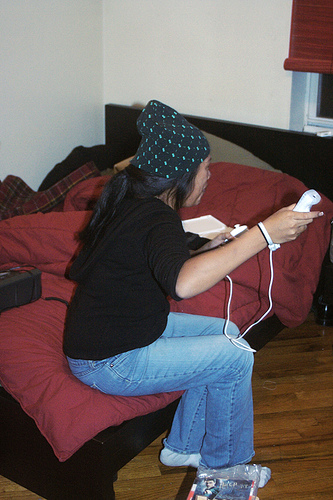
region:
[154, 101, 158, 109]
blue dot on hat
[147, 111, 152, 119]
blue dot on hat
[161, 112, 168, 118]
blue dot on hat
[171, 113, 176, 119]
blue dot on hat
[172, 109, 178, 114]
blue dot on hat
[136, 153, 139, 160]
blue dot on hat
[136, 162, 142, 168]
blue dot on hat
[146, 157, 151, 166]
blue dot on hat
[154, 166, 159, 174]
blue dot on hat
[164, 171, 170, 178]
blue dot on hat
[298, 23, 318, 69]
BLINDS AT THE WINDOW OPEN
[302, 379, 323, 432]
FLOORS ARE MADE OF HARDWOOD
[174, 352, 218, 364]
WOMAN WEARING BLUE JEANS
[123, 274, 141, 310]
LADY HAS ON A BLACK SHIRT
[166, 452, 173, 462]
LADY WEARING SOCKS ON FEET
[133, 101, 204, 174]
SCARF ON THE HEAD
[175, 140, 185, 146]
GREEN SPOTS ON THE SCARF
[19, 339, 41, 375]
BURGANDY BLANKET ON THE BED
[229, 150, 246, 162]
PILLOW UNDER THE COVER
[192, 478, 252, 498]
BOOK ON THE FLOOR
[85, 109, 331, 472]
this is a woman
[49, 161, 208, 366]
woman is wearing a black shirt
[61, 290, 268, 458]
woman wearing blue jeans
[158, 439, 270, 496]
a woman wearing socks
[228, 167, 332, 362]
woman holding a remote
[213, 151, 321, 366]
the remote is white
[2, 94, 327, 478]
woman sitting on a bed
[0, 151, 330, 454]
bed comforter is red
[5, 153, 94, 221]
plaid cover on bed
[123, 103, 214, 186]
woman wearing a hat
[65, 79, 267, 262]
woman wearing a beanie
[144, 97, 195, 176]
green polka dots on benie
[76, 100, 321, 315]
woman holding a wii controller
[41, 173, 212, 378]
woman wearing a black shirt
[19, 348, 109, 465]
red cover on bed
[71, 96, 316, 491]
woman sitting on bed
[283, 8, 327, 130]
brown blinds on window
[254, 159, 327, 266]
white wii controller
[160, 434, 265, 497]
woman wearing grey socks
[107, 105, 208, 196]
a person wearing a knitted cap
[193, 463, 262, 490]
books laying on the floor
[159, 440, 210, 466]
a person wearing socks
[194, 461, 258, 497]
books sitting next to a person's foot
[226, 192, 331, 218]
a person holding a wii remote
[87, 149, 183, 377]
a person sitting on a bed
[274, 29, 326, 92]
a shade hanging from a window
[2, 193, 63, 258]
a comforter covering a bed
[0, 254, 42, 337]
a box sitting on a bed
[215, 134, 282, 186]
pillows laying on top of a bed